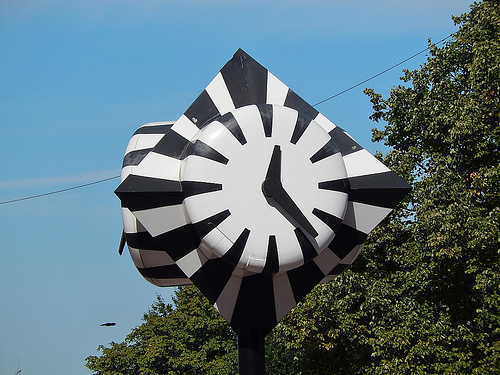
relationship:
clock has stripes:
[179, 101, 348, 273] [137, 47, 411, 334]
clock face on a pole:
[180, 101, 363, 268] [234, 332, 269, 371]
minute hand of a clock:
[268, 191, 325, 237] [114, 45, 414, 348]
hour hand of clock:
[261, 146, 294, 184] [114, 45, 414, 348]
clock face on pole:
[180, 101, 363, 268] [237, 339, 269, 369]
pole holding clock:
[236, 335, 280, 370] [179, 101, 348, 273]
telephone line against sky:
[4, 28, 482, 216] [4, 1, 468, 370]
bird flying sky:
[99, 314, 117, 329] [4, 1, 468, 370]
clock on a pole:
[179, 101, 355, 273] [237, 341, 268, 372]